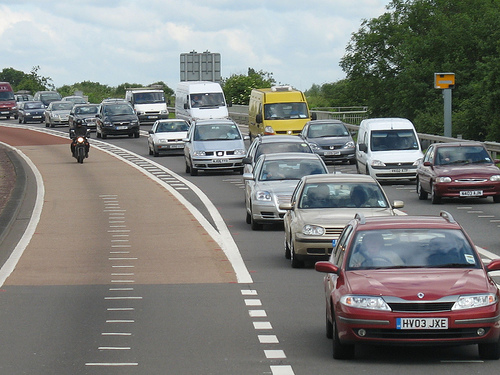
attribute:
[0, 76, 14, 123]
van — red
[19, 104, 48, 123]
car — black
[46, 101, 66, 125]
car — grey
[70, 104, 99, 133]
car — black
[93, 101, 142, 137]
van — black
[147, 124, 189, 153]
car — white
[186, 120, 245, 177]
van — grey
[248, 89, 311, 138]
van — yellow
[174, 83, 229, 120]
van — white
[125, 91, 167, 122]
van — white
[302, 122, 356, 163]
car — black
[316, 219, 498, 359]
car — red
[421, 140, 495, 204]
car — red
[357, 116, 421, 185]
van — white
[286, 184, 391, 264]
car — tan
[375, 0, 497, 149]
trees — green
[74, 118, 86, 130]
helmet — black